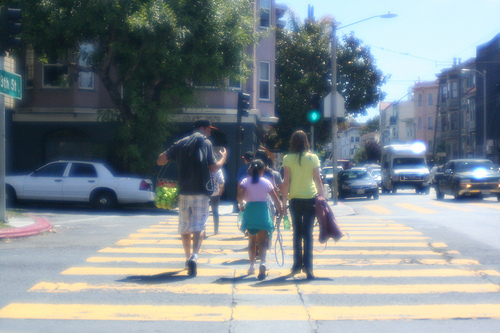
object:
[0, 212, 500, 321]
lines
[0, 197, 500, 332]
street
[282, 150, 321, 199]
shirt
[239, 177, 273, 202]
shirt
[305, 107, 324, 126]
light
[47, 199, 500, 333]
intersection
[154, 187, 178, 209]
balls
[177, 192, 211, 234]
shorts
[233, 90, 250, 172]
traffic light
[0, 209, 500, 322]
crossing area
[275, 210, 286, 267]
tennis racket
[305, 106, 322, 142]
traffic light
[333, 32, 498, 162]
buildings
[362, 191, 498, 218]
crosswalk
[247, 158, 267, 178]
head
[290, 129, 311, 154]
head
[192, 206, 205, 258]
leg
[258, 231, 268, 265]
leg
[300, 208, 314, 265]
leg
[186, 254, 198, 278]
feet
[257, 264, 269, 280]
feet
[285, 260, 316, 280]
feet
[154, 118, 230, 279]
pedestrian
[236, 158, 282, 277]
child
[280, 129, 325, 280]
adult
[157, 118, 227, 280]
adult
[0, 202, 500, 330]
crosswalk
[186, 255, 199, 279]
foot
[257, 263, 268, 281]
foot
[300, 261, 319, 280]
foot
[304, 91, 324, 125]
signal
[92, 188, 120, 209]
wheel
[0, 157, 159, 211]
car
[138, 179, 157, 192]
light